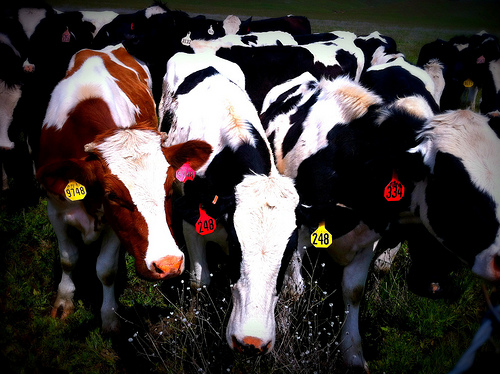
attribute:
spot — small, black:
[302, 77, 319, 93]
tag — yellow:
[306, 219, 333, 249]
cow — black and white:
[125, 32, 322, 362]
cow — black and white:
[152, 77, 322, 302]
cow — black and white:
[144, 29, 333, 354]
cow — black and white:
[32, 44, 201, 333]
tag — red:
[380, 180, 412, 208]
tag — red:
[169, 161, 196, 184]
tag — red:
[385, 175, 410, 202]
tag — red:
[195, 205, 217, 235]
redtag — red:
[193, 207, 215, 233]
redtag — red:
[172, 156, 197, 182]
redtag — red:
[385, 170, 405, 200]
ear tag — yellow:
[60, 173, 88, 205]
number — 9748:
[65, 184, 85, 199]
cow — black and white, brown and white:
[152, 41, 307, 369]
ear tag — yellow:
[307, 221, 332, 251]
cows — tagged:
[4, 1, 499, 371]